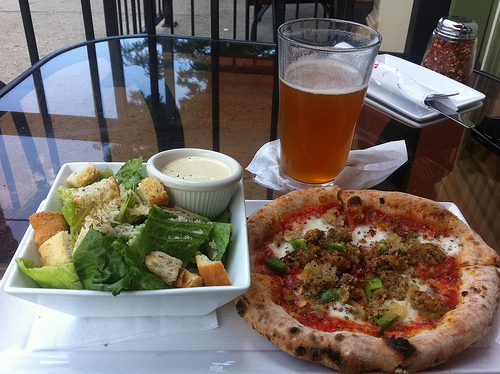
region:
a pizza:
[260, 193, 488, 365]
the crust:
[261, 311, 289, 331]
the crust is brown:
[253, 303, 285, 333]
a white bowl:
[185, 285, 219, 312]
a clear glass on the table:
[294, 40, 357, 87]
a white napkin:
[251, 152, 281, 186]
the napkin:
[263, 153, 274, 179]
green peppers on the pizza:
[363, 275, 382, 290]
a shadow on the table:
[89, 70, 229, 135]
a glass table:
[59, 71, 122, 111]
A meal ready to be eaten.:
[13, 10, 493, 364]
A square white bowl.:
[8, 139, 253, 330]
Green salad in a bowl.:
[37, 153, 239, 289]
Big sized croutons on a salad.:
[27, 152, 232, 289]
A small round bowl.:
[148, 143, 238, 205]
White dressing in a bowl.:
[166, 153, 230, 180]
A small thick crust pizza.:
[247, 180, 498, 362]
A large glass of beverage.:
[272, 9, 379, 188]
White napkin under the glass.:
[246, 38, 421, 193]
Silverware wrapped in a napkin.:
[353, 41, 490, 148]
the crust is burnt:
[378, 329, 422, 358]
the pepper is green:
[375, 307, 402, 327]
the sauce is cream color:
[188, 160, 213, 175]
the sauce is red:
[398, 212, 418, 234]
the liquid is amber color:
[295, 110, 324, 154]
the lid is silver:
[445, 16, 472, 37]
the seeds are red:
[438, 47, 454, 69]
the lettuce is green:
[153, 222, 182, 247]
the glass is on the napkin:
[315, 161, 383, 185]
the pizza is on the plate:
[238, 309, 276, 360]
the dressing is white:
[144, 131, 251, 245]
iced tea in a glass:
[265, 19, 389, 224]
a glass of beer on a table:
[280, 17, 381, 185]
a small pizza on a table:
[237, 184, 494, 372]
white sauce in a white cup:
[148, 143, 242, 210]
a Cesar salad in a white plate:
[17, 158, 232, 292]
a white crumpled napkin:
[246, 138, 407, 191]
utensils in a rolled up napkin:
[333, 39, 474, 129]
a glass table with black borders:
[0, 35, 499, 282]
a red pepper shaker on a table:
[421, 17, 478, 84]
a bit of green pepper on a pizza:
[266, 251, 285, 273]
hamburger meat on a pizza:
[303, 228, 324, 240]